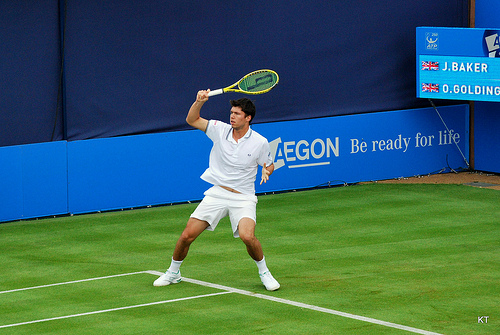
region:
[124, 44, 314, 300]
Man playing tennis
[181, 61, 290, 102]
Yellow tennis racket.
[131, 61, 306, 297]
Tennis player in a white outfit.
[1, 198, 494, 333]
Green tennis court.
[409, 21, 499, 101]
Blue scoreboard.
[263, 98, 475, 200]
Blue Aegon advertisement sign.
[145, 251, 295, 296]
White tennis shoes and socks.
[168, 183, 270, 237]
White tennis shorts.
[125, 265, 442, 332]
White lines on the tennis court.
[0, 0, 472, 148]
Dark blue wall behind the tennis player.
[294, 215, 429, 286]
the court is green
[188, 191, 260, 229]
the shorts are white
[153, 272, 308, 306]
the shoes are white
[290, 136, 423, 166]
aegon is the sponsor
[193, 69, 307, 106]
the racket is yellow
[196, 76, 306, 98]
the racket is above his head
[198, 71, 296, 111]
the racket has a white handle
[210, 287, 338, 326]
the line is white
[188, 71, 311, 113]
the racket has an initial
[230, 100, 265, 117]
his hair is black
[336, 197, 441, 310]
the carpet is green in color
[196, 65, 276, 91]
this is a racket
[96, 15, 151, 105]
the wall is blue in color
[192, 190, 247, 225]
the pair of shorts are white in color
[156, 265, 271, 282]
the shoes are white in color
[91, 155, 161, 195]
the board is white in color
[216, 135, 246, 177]
the t-shirt is white in color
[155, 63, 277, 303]
this is a man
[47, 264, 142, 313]
the carpet has markings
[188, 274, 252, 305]
the markings are white in color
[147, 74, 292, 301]
Tennis player is in motion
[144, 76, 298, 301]
Tennis player wears white cloths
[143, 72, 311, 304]
Player has white socks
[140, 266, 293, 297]
White shoes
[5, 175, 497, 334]
Tennis court is green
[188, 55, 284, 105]
Player has a racket in his right hand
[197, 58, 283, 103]
Racket is yellow and white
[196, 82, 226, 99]
Handle is white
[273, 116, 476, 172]
Words on a blue board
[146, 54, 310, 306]
Tennis player has extended arms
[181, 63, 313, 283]
A tennis player with a racquet in his hand.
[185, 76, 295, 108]
A man swinging a tennis racquet.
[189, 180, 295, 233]
The tennis player is wearing white shorts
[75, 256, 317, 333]
The tennis court has white lines.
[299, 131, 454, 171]
the blue gate has white writing.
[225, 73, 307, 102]
the racquet is yellow.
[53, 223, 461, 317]
The court is green.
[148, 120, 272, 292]
the man is standing on the court.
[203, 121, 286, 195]
The man is wearing a white shirt.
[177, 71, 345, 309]
The man is playing tennis.